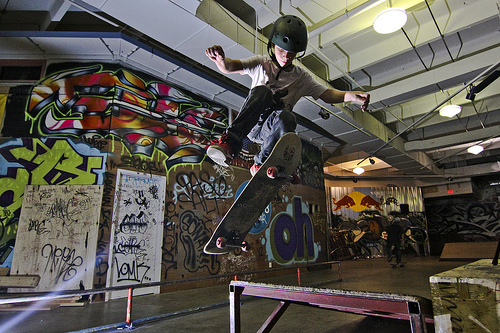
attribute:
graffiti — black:
[28, 200, 143, 301]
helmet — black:
[265, 13, 307, 65]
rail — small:
[117, 280, 154, 320]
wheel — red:
[268, 164, 279, 177]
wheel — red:
[293, 173, 300, 185]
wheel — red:
[216, 236, 228, 248]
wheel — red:
[241, 241, 251, 251]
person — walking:
[385, 214, 403, 269]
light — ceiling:
[371, 4, 408, 33]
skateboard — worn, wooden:
[201, 132, 298, 267]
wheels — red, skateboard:
[206, 159, 303, 261]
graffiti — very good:
[111, 257, 153, 282]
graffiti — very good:
[267, 193, 322, 263]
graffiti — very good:
[175, 207, 220, 272]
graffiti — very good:
[3, 136, 97, 185]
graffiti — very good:
[24, 216, 59, 238]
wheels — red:
[266, 165, 279, 180]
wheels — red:
[291, 172, 299, 183]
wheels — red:
[216, 236, 226, 248]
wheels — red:
[241, 240, 253, 252]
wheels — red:
[392, 265, 397, 269]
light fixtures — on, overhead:
[348, 8, 444, 53]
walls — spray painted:
[79, 87, 233, 208]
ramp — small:
[224, 244, 457, 329]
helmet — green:
[258, 13, 308, 48]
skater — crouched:
[208, 22, 375, 168]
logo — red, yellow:
[331, 193, 358, 210]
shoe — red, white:
[201, 145, 231, 170]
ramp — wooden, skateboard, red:
[218, 270, 430, 330]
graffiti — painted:
[0, 68, 230, 229]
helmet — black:
[258, 14, 304, 50]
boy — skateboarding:
[189, 9, 380, 181]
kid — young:
[200, 13, 387, 185]